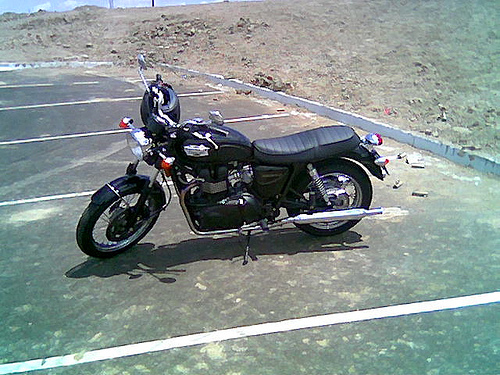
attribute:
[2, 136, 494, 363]
spot — parking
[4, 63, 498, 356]
lines — white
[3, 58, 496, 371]
lot — parking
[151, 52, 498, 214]
curb — white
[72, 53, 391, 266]
motorcycle — black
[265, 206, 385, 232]
muffler — long, silver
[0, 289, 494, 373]
line — white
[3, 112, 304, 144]
line — white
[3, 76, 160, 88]
line — white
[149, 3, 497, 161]
dirt patch — small, brown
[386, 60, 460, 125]
dirt patch — brown, small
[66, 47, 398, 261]
bike — black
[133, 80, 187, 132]
helmet — black